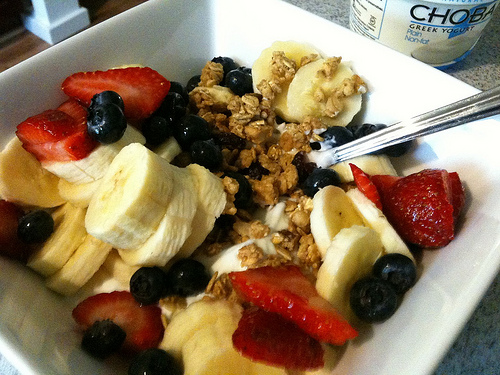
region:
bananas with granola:
[224, 19, 396, 124]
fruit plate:
[66, 71, 393, 365]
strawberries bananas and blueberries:
[13, 75, 176, 177]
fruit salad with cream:
[152, 98, 389, 343]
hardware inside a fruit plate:
[292, 80, 492, 177]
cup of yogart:
[339, 0, 496, 65]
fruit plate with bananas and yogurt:
[61, 42, 396, 371]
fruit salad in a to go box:
[7, 0, 488, 373]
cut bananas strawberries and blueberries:
[2, 77, 221, 269]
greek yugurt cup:
[352, 2, 497, 66]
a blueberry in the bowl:
[83, 102, 123, 144]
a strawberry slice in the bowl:
[224, 262, 359, 347]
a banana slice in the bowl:
[82, 140, 174, 252]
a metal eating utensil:
[301, 81, 497, 168]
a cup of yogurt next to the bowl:
[345, 0, 496, 72]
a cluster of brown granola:
[267, 47, 297, 79]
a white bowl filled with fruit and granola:
[0, 0, 496, 373]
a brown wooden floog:
[0, 0, 150, 77]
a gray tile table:
[280, 0, 497, 372]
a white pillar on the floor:
[17, 1, 93, 46]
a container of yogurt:
[348, 0, 494, 65]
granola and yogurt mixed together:
[223, 207, 315, 275]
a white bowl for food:
[0, 2, 465, 367]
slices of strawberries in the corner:
[351, 160, 456, 245]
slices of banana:
[92, 141, 217, 267]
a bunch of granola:
[200, 58, 298, 176]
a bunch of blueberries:
[147, 91, 218, 161]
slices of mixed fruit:
[20, 70, 225, 281]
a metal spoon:
[313, 92, 489, 168]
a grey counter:
[453, 284, 493, 373]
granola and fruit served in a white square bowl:
[5, 33, 481, 340]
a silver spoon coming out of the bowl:
[295, 73, 498, 173]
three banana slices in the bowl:
[91, 153, 225, 257]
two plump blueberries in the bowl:
[349, 244, 415, 320]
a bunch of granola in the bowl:
[196, 87, 299, 199]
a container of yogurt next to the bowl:
[344, 1, 497, 66]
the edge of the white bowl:
[91, 10, 343, 45]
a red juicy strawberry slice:
[231, 263, 348, 347]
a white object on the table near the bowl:
[9, 0, 105, 43]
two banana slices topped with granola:
[252, 46, 367, 126]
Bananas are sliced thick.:
[24, 139, 225, 270]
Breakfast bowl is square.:
[0, 0, 497, 372]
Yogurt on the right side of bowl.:
[0, 1, 498, 372]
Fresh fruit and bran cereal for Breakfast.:
[2, 35, 470, 374]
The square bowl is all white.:
[1, 1, 498, 371]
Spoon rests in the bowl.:
[2, 0, 496, 373]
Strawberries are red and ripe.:
[11, 57, 177, 176]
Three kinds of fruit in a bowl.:
[3, 35, 267, 231]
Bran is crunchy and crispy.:
[131, 32, 367, 340]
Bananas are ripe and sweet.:
[1, 0, 421, 374]